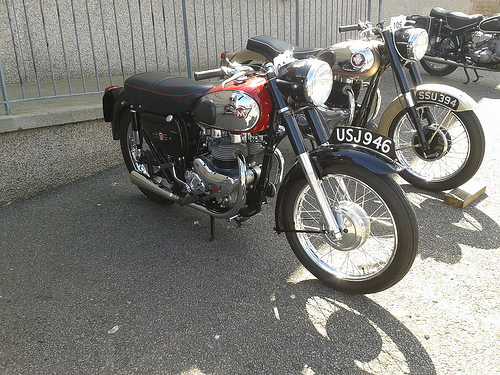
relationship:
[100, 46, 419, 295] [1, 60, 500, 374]
bike parked on street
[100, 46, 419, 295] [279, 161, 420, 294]
bike has front tire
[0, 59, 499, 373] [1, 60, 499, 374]
shadow showing on ground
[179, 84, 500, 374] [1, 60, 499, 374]
light hitting ground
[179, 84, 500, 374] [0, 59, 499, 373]
light next to shadow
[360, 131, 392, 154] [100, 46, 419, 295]
number on front of bike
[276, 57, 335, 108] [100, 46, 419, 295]
light on front of bike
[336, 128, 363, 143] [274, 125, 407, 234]
letters printed on fender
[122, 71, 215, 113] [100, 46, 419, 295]
seat on top of bike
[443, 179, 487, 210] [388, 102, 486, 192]
block under tire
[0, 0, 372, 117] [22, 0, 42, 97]
railing has rod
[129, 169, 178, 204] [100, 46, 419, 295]
exhaust pipe on side of bike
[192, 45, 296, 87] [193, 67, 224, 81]
handlebar has handle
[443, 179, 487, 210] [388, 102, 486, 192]
block blocking tire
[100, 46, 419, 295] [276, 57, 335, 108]
bike has light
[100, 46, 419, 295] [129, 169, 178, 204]
bike has exhaust pipe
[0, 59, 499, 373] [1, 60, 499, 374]
shadow sitting on ground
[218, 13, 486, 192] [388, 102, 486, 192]
motorcycle has tire